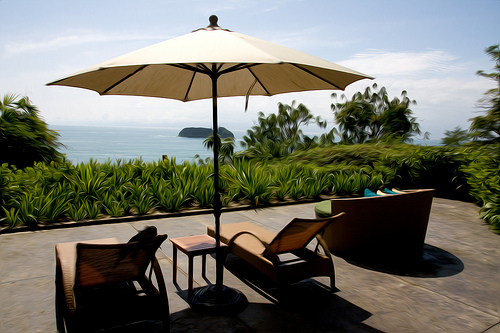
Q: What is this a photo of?
A: Patio furniture.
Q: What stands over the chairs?
A: Umbrella.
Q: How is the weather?
A: Sunny.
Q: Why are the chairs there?
A: Relaxation.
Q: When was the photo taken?
A: Daytime.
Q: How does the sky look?
A: Cloudy.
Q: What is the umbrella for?
A: Sun protection.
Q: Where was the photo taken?
A: Island resort.